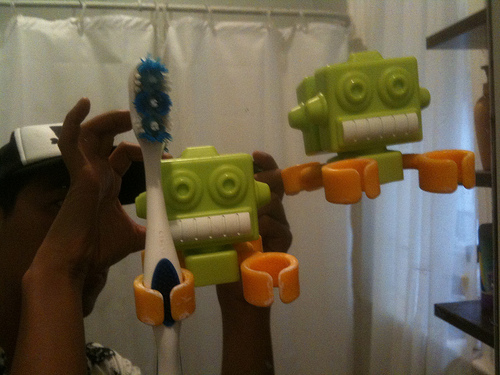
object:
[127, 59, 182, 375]
toothbrush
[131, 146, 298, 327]
toy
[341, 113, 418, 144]
teeth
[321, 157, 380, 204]
hand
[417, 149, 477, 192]
hand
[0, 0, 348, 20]
rail bar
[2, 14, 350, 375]
curtain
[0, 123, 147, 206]
hat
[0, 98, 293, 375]
boy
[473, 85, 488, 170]
bottle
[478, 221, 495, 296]
can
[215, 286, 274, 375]
arm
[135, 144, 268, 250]
robot head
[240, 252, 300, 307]
hand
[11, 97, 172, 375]
hand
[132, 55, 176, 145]
bristles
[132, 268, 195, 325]
clip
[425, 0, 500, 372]
shelf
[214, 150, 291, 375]
hand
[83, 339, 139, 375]
shirt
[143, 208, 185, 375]
handle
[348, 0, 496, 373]
curtain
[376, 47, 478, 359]
window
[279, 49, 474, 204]
toothbrush holder